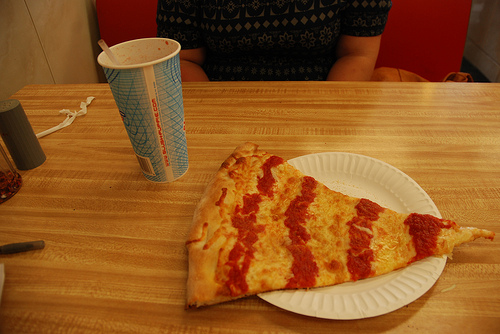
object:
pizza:
[183, 141, 495, 312]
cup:
[97, 38, 189, 184]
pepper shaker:
[0, 99, 47, 172]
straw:
[98, 39, 122, 66]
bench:
[97, 0, 473, 83]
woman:
[156, 0, 392, 81]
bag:
[372, 66, 473, 82]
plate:
[256, 151, 448, 321]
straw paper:
[36, 96, 96, 139]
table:
[1, 81, 500, 334]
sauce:
[405, 214, 444, 254]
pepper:
[0, 144, 22, 204]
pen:
[0, 240, 45, 255]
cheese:
[375, 225, 403, 266]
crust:
[188, 177, 237, 305]